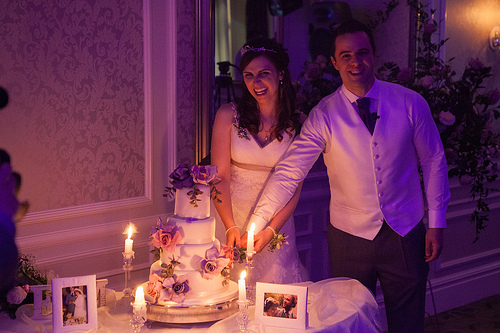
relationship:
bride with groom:
[207, 37, 301, 270] [271, 17, 456, 293]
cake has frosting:
[148, 165, 240, 320] [175, 224, 222, 280]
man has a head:
[271, 17, 456, 293] [330, 7, 392, 96]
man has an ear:
[271, 17, 456, 293] [322, 48, 347, 76]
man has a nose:
[271, 17, 456, 293] [345, 55, 366, 69]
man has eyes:
[271, 17, 456, 293] [336, 49, 379, 67]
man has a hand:
[271, 17, 456, 293] [426, 224, 453, 279]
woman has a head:
[207, 37, 301, 270] [231, 39, 295, 120]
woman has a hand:
[207, 37, 301, 270] [220, 211, 244, 286]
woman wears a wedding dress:
[207, 37, 301, 270] [213, 100, 325, 295]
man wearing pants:
[271, 17, 456, 293] [321, 220, 437, 333]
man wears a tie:
[271, 17, 456, 293] [352, 93, 380, 144]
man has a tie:
[271, 17, 456, 293] [352, 93, 380, 144]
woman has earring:
[207, 37, 301, 270] [277, 75, 290, 86]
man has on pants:
[271, 17, 456, 293] [321, 220, 437, 333]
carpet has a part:
[414, 290, 498, 333] [463, 284, 499, 328]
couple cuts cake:
[203, 29, 427, 300] [148, 165, 240, 320]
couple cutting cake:
[203, 29, 427, 300] [148, 165, 240, 320]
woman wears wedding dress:
[207, 37, 301, 270] [213, 100, 325, 295]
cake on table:
[148, 165, 240, 320] [44, 262, 372, 327]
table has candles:
[44, 262, 372, 327] [107, 216, 284, 317]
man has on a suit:
[271, 17, 456, 293] [289, 84, 453, 313]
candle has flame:
[116, 222, 146, 291] [116, 223, 144, 243]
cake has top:
[148, 165, 240, 320] [173, 173, 232, 222]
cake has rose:
[148, 165, 240, 320] [146, 225, 184, 257]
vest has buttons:
[296, 104, 425, 249] [370, 135, 390, 210]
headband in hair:
[237, 40, 290, 67] [238, 42, 290, 149]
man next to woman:
[271, 17, 456, 293] [207, 37, 301, 270]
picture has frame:
[253, 279, 308, 330] [246, 284, 309, 323]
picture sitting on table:
[253, 279, 308, 330] [44, 262, 372, 327]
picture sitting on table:
[50, 265, 99, 332] [44, 262, 372, 327]